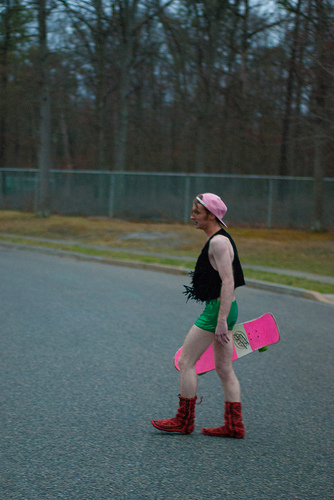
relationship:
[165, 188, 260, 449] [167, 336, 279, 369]
man with skateboard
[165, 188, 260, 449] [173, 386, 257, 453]
man wearing shoes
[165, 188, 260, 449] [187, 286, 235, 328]
man wearing shorts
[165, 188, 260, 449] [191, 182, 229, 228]
man wearing ball cap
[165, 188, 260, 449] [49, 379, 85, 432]
man in road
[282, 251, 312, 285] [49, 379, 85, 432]
sidewalk by road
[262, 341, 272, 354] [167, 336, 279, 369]
wheels on skateboard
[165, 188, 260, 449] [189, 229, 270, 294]
man wearing vest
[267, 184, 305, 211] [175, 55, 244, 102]
fence by trees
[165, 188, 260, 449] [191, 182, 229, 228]
man in ball cap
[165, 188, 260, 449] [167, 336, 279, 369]
man carrying skateboard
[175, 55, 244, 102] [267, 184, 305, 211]
trees behind fence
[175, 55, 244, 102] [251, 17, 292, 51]
trees with branches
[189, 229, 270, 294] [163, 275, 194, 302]
vest has tassels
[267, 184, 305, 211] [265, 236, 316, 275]
fence by grass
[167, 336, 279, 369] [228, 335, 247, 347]
skateboard has design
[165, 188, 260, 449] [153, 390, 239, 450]
man wearing boots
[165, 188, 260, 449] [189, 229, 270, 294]
man in vest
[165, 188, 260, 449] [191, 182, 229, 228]
man with ball cap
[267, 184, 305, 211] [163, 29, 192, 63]
fence in background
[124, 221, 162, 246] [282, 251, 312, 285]
part of sidewalk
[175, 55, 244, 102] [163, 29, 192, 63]
trees in background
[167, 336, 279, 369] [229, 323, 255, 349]
skateboard has line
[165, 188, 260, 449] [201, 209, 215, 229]
man has sideburns